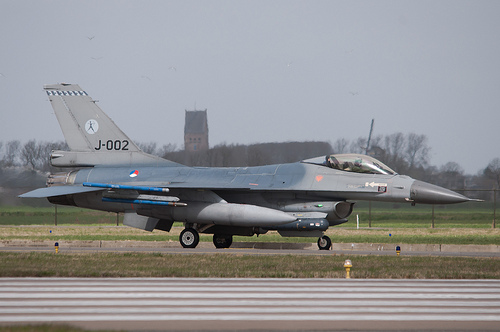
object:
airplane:
[19, 83, 484, 251]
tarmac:
[1, 241, 500, 259]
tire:
[179, 227, 201, 248]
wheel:
[179, 228, 200, 248]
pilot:
[354, 159, 365, 167]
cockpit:
[300, 154, 402, 176]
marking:
[343, 259, 353, 279]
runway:
[0, 277, 499, 330]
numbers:
[94, 138, 130, 152]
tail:
[17, 83, 186, 213]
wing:
[117, 181, 279, 191]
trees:
[0, 141, 29, 172]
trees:
[370, 134, 432, 168]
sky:
[1, 1, 500, 175]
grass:
[373, 222, 498, 244]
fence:
[0, 203, 499, 226]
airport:
[0, 204, 499, 329]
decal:
[128, 169, 139, 178]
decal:
[84, 118, 100, 134]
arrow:
[365, 180, 389, 187]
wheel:
[212, 233, 233, 248]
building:
[165, 110, 333, 168]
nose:
[413, 181, 485, 205]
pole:
[356, 213, 361, 229]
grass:
[1, 251, 92, 279]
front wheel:
[316, 235, 331, 250]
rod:
[82, 181, 170, 192]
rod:
[103, 196, 188, 207]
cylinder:
[136, 202, 297, 227]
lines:
[1, 276, 500, 324]